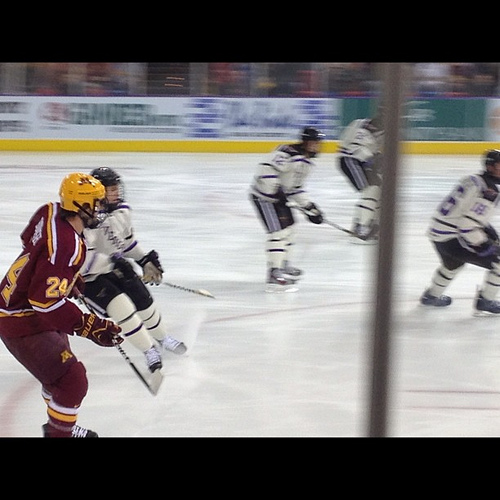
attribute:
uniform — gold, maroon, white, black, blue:
[44, 217, 58, 259]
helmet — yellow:
[55, 160, 106, 218]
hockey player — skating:
[13, 156, 112, 489]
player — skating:
[413, 147, 499, 326]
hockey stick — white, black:
[303, 202, 379, 256]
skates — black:
[413, 288, 500, 320]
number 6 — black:
[357, 130, 369, 142]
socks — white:
[271, 252, 283, 267]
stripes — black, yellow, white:
[267, 240, 286, 250]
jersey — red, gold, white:
[43, 249, 92, 274]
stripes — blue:
[126, 324, 145, 340]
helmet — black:
[286, 121, 327, 139]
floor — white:
[206, 338, 318, 382]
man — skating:
[224, 123, 333, 298]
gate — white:
[87, 97, 289, 133]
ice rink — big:
[162, 197, 261, 314]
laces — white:
[274, 264, 292, 275]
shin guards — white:
[99, 284, 141, 316]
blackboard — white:
[220, 101, 308, 129]